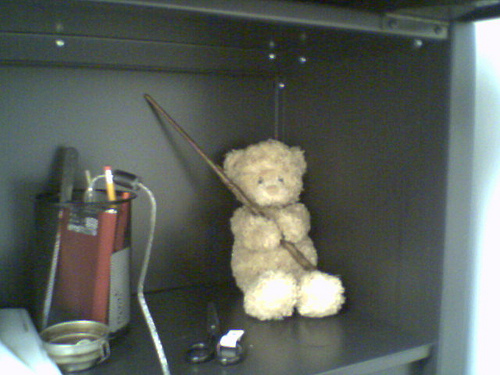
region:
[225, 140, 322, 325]
this is a teddy bear doll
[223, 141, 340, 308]
the teddy bear is sitted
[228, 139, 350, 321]
the teddy bear is yellow in color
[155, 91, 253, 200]
the teddy bear is holding a stick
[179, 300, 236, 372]
a pair of scissors is beside the teddy bear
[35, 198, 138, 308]
a glass is on the table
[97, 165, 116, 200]
this is a pencil in the glass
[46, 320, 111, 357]
this is the top of the glass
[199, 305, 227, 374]
the scissors is metalic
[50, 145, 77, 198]
this is a screw driver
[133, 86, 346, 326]
brown fuzzy teddy bear holding brown stick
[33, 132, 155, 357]
clear glass jar with tools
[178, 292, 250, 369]
silver scissors with grey handle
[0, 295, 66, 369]
square white stack of paper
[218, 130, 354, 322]
teddy bear sitting on silver shelf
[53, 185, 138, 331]
red tools inside jar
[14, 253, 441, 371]
silver shelf under teddy bear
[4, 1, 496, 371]
metal and wood cupboard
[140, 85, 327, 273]
long brown magic wand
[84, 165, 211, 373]
silver metal hook hanging from jar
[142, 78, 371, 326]
a teddy bear holding a drum stick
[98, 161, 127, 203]
a yellow pencil with a red eraser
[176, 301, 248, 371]
a pair of scissors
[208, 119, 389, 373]
a teddy bear sitting on a shelf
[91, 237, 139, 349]
a white business card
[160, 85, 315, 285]
a brown drum stick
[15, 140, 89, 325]
a screwdriver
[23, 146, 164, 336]
a pencil in a container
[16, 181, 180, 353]
a black round container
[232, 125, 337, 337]
a light brown teddy bear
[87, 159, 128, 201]
pencil eraser sticking out of cup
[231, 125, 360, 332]
light brown teddy bear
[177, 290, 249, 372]
pair of scissors on a shelf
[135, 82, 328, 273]
wooden stick held by teddy bear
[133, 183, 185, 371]
silver cable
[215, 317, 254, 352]
white paper wrapped around scissor handle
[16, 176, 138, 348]
mesh holding cup full of office supplies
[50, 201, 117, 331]
small notebook in mesh cup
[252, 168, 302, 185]
eyes sewn on to the teddy bear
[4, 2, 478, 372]
items on a metal shelf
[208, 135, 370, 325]
yellow fuzzy teddy bear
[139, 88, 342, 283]
chopstick in teddy bear arms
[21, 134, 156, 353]
black metal pen and pencil holder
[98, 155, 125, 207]
bright yellow pencil with pink eraser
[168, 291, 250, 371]
black and metal scissors with white tag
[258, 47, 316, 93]
three metal rivets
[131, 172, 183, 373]
silver charging chord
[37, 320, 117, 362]
golden metal tin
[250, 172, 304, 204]
black eyes and button nose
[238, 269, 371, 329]
bright glare on white teddy bear feet